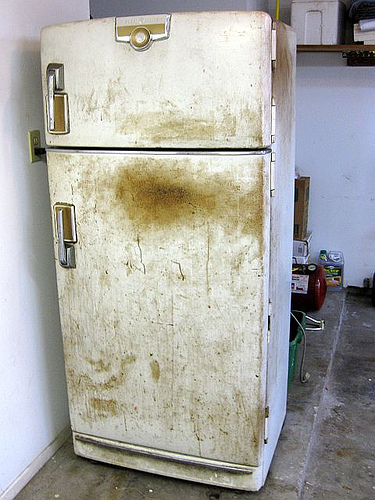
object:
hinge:
[269, 27, 278, 65]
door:
[38, 8, 272, 150]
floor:
[12, 287, 375, 500]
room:
[0, 1, 373, 500]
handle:
[55, 204, 77, 272]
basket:
[286, 308, 307, 386]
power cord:
[33, 144, 46, 158]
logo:
[112, 13, 171, 54]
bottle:
[318, 248, 329, 266]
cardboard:
[292, 174, 310, 242]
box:
[290, 228, 314, 259]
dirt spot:
[113, 156, 265, 247]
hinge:
[266, 313, 271, 335]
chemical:
[325, 248, 346, 267]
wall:
[290, 49, 373, 289]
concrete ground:
[10, 287, 374, 499]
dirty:
[58, 287, 263, 466]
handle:
[44, 61, 71, 137]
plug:
[26, 128, 44, 165]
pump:
[289, 260, 328, 315]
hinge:
[269, 96, 275, 147]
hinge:
[261, 412, 269, 447]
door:
[43, 148, 269, 470]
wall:
[0, 2, 95, 500]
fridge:
[38, 8, 298, 495]